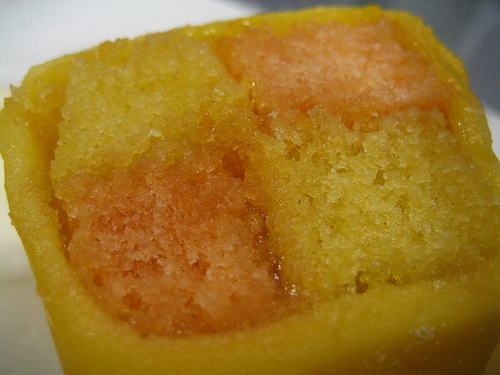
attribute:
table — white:
[1, 0, 498, 374]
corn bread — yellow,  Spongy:
[2, 7, 494, 371]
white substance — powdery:
[409, 314, 440, 357]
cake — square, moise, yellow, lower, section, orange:
[1, 2, 498, 372]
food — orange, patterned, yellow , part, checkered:
[3, 2, 498, 372]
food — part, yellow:
[327, 105, 399, 208]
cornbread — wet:
[3, 23, 462, 371]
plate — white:
[50, 10, 175, 65]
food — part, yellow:
[31, 32, 478, 342]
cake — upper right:
[64, 49, 236, 172]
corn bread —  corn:
[12, 46, 473, 323]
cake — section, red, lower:
[52, 133, 304, 341]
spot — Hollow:
[127, 183, 252, 289]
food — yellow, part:
[17, 54, 484, 364]